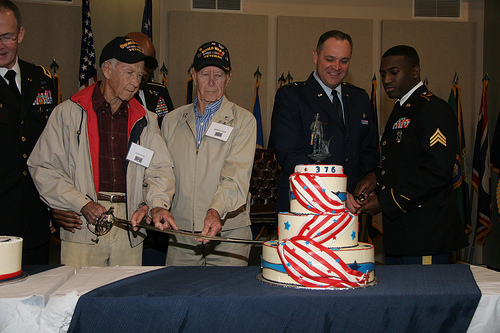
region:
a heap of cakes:
[286, 166, 351, 279]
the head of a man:
[383, 49, 415, 94]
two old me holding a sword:
[83, 35, 239, 266]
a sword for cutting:
[143, 224, 264, 247]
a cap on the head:
[189, 42, 232, 70]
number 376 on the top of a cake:
[315, 164, 337, 174]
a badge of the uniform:
[429, 130, 449, 150]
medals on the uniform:
[395, 118, 410, 128]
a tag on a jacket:
[129, 142, 149, 167]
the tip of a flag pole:
[253, 64, 262, 76]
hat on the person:
[110, 40, 151, 61]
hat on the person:
[191, 42, 234, 71]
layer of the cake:
[282, 165, 350, 213]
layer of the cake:
[257, 215, 357, 242]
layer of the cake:
[258, 237, 377, 292]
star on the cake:
[348, 233, 358, 242]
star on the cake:
[278, 218, 295, 233]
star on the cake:
[348, 258, 363, 274]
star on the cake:
[337, 190, 348, 205]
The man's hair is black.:
[378, 46, 424, 100]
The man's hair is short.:
[378, 43, 420, 99]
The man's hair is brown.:
[306, 31, 358, 88]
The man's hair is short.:
[313, 28, 352, 85]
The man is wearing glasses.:
[0, 2, 24, 69]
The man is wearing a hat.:
[98, 37, 156, 102]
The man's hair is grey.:
[98, 40, 160, 100]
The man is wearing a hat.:
[187, 38, 232, 101]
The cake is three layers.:
[256, 166, 378, 289]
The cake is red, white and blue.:
[258, 163, 375, 290]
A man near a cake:
[367, 51, 469, 266]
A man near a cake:
[292, 50, 366, 231]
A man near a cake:
[184, 38, 251, 265]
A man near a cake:
[67, 45, 144, 257]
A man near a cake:
[1, 21, 51, 265]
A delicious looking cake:
[284, 140, 382, 311]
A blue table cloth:
[374, 263, 464, 318]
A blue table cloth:
[142, 268, 246, 329]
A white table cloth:
[18, 280, 75, 318]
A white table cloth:
[471, 273, 498, 315]